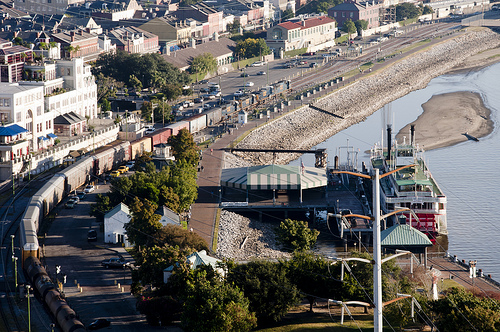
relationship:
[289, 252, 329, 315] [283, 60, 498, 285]
tree near lake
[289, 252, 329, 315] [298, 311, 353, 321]
tree has a shadow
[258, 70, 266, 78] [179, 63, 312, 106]
car on street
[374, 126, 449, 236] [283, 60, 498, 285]
boat in lake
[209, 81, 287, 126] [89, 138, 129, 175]
train has a car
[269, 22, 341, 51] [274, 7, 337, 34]
building has a roof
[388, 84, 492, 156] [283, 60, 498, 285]
island near lake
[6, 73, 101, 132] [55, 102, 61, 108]
building has a window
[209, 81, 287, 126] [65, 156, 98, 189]
train has a compartment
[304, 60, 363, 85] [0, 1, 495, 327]
train track on photo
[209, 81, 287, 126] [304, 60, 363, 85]
train on train track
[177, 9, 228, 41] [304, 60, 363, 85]
house near train track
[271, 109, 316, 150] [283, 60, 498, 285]
gravel near lake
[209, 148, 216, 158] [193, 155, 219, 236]
person walking on sidewalk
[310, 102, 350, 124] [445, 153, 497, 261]
sand bar near a lake